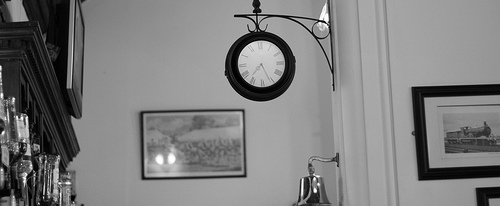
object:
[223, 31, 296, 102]
clock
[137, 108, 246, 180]
picture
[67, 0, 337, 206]
wall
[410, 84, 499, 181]
picture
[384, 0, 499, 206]
wall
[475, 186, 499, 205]
picture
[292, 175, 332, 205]
bell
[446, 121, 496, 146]
train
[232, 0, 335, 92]
rod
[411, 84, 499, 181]
frame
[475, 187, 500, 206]
frame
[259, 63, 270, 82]
minute hand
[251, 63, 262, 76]
hour hand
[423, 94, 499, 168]
matte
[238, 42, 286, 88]
roman numerals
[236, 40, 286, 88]
face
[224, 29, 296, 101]
clock frame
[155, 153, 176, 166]
light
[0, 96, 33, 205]
wine bottles